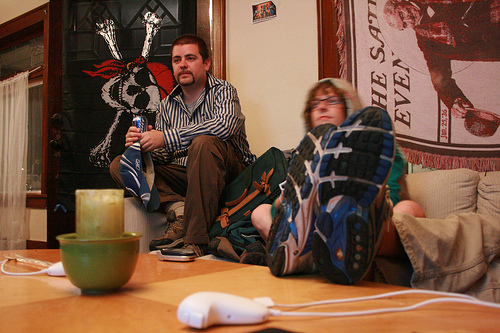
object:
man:
[107, 33, 259, 264]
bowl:
[53, 186, 145, 295]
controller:
[173, 288, 282, 331]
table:
[0, 248, 500, 333]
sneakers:
[311, 104, 400, 286]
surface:
[0, 247, 500, 333]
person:
[249, 74, 429, 287]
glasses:
[305, 95, 343, 109]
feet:
[310, 104, 398, 286]